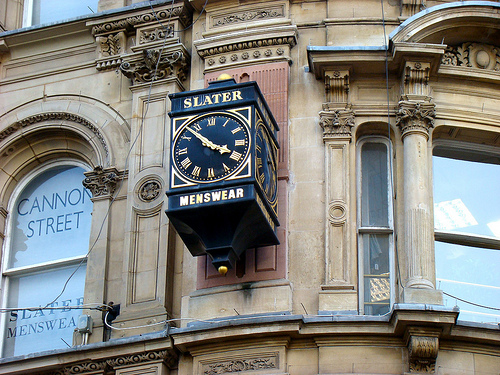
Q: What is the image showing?
A: It is showing a street.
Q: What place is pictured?
A: It is a street.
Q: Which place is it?
A: It is a street.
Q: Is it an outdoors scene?
A: Yes, it is outdoors.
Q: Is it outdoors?
A: Yes, it is outdoors.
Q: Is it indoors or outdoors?
A: It is outdoors.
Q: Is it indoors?
A: No, it is outdoors.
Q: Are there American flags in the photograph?
A: No, there are no American flags.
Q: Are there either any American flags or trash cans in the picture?
A: No, there are no American flags or trash cans.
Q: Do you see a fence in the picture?
A: No, there are no fences.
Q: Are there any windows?
A: Yes, there is a window.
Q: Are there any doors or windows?
A: Yes, there is a window.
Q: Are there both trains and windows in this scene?
A: No, there is a window but no trains.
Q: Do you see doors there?
A: No, there are no doors.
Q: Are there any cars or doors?
A: No, there are no doors or cars.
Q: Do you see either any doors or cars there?
A: No, there are no doors or cars.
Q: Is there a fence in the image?
A: No, there are no fences.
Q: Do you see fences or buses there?
A: No, there are no fences or buses.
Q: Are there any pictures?
A: No, there are no pictures.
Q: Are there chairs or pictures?
A: No, there are no pictures or chairs.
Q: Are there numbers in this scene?
A: Yes, there are numbers.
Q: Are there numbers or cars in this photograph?
A: Yes, there are numbers.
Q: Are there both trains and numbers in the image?
A: No, there are numbers but no trains.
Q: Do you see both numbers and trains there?
A: No, there are numbers but no trains.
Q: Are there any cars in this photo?
A: No, there are no cars.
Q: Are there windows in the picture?
A: Yes, there is a window.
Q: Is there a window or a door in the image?
A: Yes, there is a window.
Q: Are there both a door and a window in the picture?
A: No, there is a window but no doors.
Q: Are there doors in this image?
A: No, there are no doors.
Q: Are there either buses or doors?
A: No, there are no doors or buses.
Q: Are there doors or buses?
A: No, there are no doors or buses.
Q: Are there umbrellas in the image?
A: No, there are no umbrellas.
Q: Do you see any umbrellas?
A: No, there are no umbrellas.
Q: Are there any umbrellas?
A: No, there are no umbrellas.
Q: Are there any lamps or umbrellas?
A: No, there are no umbrellas or lamps.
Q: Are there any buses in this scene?
A: No, there are no buses.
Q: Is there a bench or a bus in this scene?
A: No, there are no buses or benches.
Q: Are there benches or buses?
A: No, there are no buses or benches.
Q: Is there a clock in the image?
A: Yes, there is a clock.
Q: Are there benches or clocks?
A: Yes, there is a clock.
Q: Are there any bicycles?
A: No, there are no bicycles.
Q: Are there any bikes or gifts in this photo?
A: No, there are no bikes or gifts.